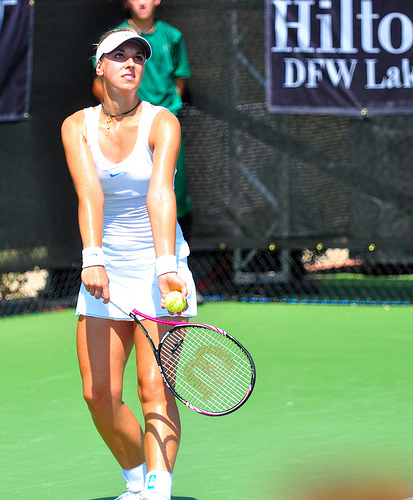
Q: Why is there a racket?
A: Hit ball.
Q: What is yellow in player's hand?
A: Tennis ball.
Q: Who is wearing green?
A: Person in background.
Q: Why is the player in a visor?
A: Shade on face.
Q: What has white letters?
A: Sign in back.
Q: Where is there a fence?
A: Background.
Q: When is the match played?
A: Sunny day.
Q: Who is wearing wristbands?
A: Player.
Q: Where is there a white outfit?
A: On player.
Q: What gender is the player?
A: Female.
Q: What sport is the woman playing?
A: Tennis.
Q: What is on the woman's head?
A: A sun visor.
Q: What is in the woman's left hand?
A: A tennis ball.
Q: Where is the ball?
A: In the woman's hand.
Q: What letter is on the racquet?
A: W.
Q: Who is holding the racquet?
A: The woman.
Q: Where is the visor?
A: On the woman's head.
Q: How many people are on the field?
A: 2.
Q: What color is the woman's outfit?
A: White.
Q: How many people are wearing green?
A: 1.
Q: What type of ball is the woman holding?
A: Tennis ball.